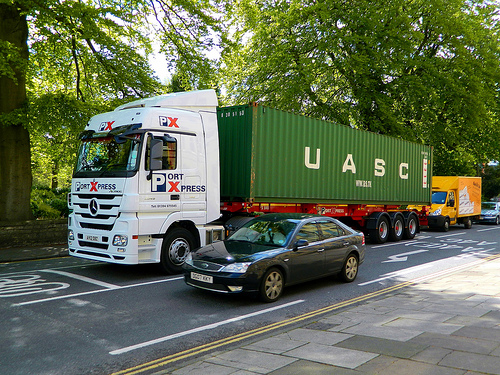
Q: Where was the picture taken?
A: It was taken at the road.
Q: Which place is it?
A: It is a road.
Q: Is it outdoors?
A: Yes, it is outdoors.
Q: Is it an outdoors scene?
A: Yes, it is outdoors.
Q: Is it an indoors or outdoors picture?
A: It is outdoors.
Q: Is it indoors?
A: No, it is outdoors.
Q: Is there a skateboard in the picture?
A: No, there are no skateboards.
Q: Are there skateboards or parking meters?
A: No, there are no skateboards or parking meters.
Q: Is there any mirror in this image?
A: Yes, there is a mirror.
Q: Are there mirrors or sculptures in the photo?
A: Yes, there is a mirror.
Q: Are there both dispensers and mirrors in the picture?
A: No, there is a mirror but no dispensers.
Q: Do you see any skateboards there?
A: No, there are no skateboards.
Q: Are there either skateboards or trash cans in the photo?
A: No, there are no skateboards or trash cans.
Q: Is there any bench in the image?
A: No, there are no benches.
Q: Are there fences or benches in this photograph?
A: No, there are no benches or fences.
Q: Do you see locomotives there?
A: No, there are no locomotives.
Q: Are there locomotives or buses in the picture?
A: No, there are no locomotives or buses.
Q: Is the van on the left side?
A: No, the van is on the right of the image.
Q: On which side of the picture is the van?
A: The van is on the right of the image.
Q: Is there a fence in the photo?
A: No, there are no fences.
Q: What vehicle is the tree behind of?
A: The tree is behind the car.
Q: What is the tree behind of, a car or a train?
A: The tree is behind a car.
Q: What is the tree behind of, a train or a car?
A: The tree is behind a car.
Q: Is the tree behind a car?
A: Yes, the tree is behind a car.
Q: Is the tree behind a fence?
A: No, the tree is behind a car.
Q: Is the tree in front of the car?
A: No, the tree is behind the car.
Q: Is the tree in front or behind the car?
A: The tree is behind the car.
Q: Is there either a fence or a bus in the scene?
A: No, there are no fences or buses.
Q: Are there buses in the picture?
A: No, there are no buses.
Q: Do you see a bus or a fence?
A: No, there are no buses or fences.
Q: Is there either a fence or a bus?
A: No, there are no buses or fences.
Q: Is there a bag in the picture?
A: No, there are no bags.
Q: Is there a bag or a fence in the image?
A: No, there are no bags or fences.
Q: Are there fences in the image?
A: No, there are no fences.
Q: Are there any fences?
A: No, there are no fences.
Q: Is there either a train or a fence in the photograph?
A: No, there are no fences or trains.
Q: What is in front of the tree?
A: The car is in front of the tree.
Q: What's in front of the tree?
A: The car is in front of the tree.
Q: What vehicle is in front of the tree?
A: The vehicle is a car.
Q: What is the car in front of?
A: The car is in front of the tree.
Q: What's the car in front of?
A: The car is in front of the tree.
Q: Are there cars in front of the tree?
A: Yes, there is a car in front of the tree.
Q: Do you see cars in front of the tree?
A: Yes, there is a car in front of the tree.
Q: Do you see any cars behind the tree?
A: No, the car is in front of the tree.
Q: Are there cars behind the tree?
A: No, the car is in front of the tree.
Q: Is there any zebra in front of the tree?
A: No, there is a car in front of the tree.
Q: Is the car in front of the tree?
A: Yes, the car is in front of the tree.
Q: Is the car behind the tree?
A: No, the car is in front of the tree.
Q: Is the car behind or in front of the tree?
A: The car is in front of the tree.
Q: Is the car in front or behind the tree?
A: The car is in front of the tree.